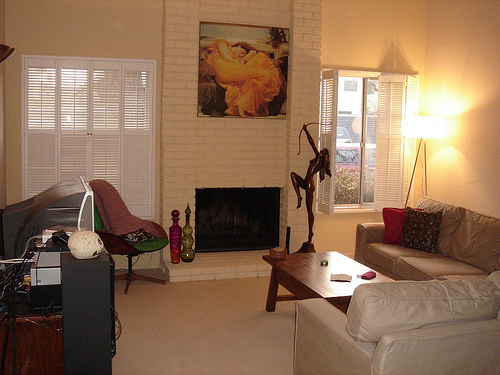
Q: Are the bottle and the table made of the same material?
A: No, the bottle is made of glass and the table is made of wood.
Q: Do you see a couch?
A: Yes, there is a couch.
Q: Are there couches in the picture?
A: Yes, there is a couch.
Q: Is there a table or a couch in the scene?
A: Yes, there is a couch.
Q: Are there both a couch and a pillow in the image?
A: Yes, there are both a couch and a pillow.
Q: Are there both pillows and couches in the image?
A: Yes, there are both a couch and a pillow.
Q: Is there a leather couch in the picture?
A: Yes, there is a couch that is made of leather.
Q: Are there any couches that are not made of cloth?
A: Yes, there is a couch that is made of leather.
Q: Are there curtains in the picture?
A: No, there are no curtains.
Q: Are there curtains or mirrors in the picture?
A: No, there are no curtains or mirrors.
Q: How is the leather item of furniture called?
A: The piece of furniture is a couch.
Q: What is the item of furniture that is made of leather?
A: The piece of furniture is a couch.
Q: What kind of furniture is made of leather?
A: The furniture is a couch.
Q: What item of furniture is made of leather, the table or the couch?
A: The couch is made of leather.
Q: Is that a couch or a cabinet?
A: That is a couch.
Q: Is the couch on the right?
A: Yes, the couch is on the right of the image.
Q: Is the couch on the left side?
A: No, the couch is on the right of the image.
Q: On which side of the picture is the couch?
A: The couch is on the right of the image.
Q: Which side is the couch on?
A: The couch is on the right of the image.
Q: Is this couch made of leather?
A: Yes, the couch is made of leather.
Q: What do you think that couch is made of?
A: The couch is made of leather.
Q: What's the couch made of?
A: The couch is made of leather.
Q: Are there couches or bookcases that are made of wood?
A: No, there is a couch but it is made of leather.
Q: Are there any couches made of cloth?
A: No, there is a couch but it is made of leather.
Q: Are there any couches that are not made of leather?
A: No, there is a couch but it is made of leather.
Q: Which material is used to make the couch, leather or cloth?
A: The couch is made of leather.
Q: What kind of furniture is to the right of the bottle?
A: The piece of furniture is a couch.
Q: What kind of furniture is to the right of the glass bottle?
A: The piece of furniture is a couch.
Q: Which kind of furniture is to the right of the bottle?
A: The piece of furniture is a couch.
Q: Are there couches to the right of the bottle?
A: Yes, there is a couch to the right of the bottle.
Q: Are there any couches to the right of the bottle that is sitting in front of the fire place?
A: Yes, there is a couch to the right of the bottle.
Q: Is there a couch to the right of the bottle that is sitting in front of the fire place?
A: Yes, there is a couch to the right of the bottle.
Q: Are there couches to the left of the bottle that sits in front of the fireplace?
A: No, the couch is to the right of the bottle.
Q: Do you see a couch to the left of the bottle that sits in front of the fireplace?
A: No, the couch is to the right of the bottle.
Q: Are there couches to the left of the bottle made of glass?
A: No, the couch is to the right of the bottle.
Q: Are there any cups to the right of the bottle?
A: No, there is a couch to the right of the bottle.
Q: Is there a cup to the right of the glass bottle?
A: No, there is a couch to the right of the bottle.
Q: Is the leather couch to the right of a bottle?
A: Yes, the couch is to the right of a bottle.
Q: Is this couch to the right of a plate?
A: No, the couch is to the right of a bottle.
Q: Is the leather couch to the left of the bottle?
A: No, the couch is to the right of the bottle.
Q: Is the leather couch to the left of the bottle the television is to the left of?
A: No, the couch is to the right of the bottle.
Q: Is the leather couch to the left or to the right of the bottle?
A: The couch is to the right of the bottle.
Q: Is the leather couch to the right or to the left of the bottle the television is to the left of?
A: The couch is to the right of the bottle.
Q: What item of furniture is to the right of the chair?
A: The piece of furniture is a couch.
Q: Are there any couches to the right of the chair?
A: Yes, there is a couch to the right of the chair.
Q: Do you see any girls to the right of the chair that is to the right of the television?
A: No, there is a couch to the right of the chair.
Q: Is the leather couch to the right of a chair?
A: Yes, the couch is to the right of a chair.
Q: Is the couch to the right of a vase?
A: No, the couch is to the right of a chair.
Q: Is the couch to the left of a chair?
A: No, the couch is to the right of a chair.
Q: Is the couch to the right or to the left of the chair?
A: The couch is to the right of the chair.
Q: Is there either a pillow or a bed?
A: Yes, there is a pillow.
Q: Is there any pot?
A: No, there are no pots.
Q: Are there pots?
A: No, there are no pots.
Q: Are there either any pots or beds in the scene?
A: No, there are no pots or beds.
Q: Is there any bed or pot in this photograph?
A: No, there are no pots or beds.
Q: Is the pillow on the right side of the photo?
A: Yes, the pillow is on the right of the image.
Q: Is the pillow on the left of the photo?
A: No, the pillow is on the right of the image.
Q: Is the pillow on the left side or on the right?
A: The pillow is on the right of the image.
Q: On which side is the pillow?
A: The pillow is on the right of the image.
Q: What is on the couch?
A: The pillow is on the couch.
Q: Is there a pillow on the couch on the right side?
A: Yes, there is a pillow on the couch.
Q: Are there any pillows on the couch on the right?
A: Yes, there is a pillow on the couch.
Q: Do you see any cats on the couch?
A: No, there is a pillow on the couch.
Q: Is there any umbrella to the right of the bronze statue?
A: No, there is a pillow to the right of the statue.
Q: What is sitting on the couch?
A: The pillow is sitting on the couch.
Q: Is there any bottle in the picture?
A: Yes, there is a bottle.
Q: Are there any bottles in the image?
A: Yes, there is a bottle.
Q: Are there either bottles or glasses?
A: Yes, there is a bottle.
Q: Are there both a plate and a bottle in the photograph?
A: No, there is a bottle but no plates.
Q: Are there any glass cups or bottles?
A: Yes, there is a glass bottle.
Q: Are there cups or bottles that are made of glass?
A: Yes, the bottle is made of glass.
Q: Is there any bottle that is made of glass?
A: Yes, there is a bottle that is made of glass.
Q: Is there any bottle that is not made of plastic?
A: Yes, there is a bottle that is made of glass.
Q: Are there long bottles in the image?
A: Yes, there is a long bottle.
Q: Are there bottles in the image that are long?
A: Yes, there is a bottle that is long.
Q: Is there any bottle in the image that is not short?
A: Yes, there is a long bottle.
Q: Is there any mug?
A: No, there are no mugs.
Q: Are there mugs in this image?
A: No, there are no mugs.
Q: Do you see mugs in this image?
A: No, there are no mugs.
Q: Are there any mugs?
A: No, there are no mugs.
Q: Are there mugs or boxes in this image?
A: No, there are no mugs or boxes.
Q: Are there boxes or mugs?
A: No, there are no mugs or boxes.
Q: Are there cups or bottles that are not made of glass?
A: No, there is a bottle but it is made of glass.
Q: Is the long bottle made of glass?
A: Yes, the bottle is made of glass.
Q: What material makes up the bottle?
A: The bottle is made of glass.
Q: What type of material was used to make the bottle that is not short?
A: The bottle is made of glass.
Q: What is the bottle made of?
A: The bottle is made of glass.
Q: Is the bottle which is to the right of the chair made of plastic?
A: No, the bottle is made of glass.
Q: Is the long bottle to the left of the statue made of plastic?
A: No, the bottle is made of glass.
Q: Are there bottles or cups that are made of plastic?
A: No, there is a bottle but it is made of glass.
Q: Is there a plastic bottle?
A: No, there is a bottle but it is made of glass.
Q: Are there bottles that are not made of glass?
A: No, there is a bottle but it is made of glass.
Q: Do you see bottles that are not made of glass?
A: No, there is a bottle but it is made of glass.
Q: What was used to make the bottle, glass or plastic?
A: The bottle is made of glass.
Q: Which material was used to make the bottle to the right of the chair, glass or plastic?
A: The bottle is made of glass.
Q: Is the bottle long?
A: Yes, the bottle is long.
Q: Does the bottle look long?
A: Yes, the bottle is long.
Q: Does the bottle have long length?
A: Yes, the bottle is long.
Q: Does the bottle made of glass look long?
A: Yes, the bottle is long.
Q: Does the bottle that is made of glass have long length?
A: Yes, the bottle is long.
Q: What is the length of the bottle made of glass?
A: The bottle is long.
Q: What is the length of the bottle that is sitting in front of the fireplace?
A: The bottle is long.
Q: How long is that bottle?
A: The bottle is long.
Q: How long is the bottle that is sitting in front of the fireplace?
A: The bottle is long.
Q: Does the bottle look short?
A: No, the bottle is long.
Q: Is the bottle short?
A: No, the bottle is long.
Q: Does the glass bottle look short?
A: No, the bottle is long.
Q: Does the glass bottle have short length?
A: No, the bottle is long.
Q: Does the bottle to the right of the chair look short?
A: No, the bottle is long.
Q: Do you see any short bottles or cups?
A: No, there is a bottle but it is long.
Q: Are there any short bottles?
A: No, there is a bottle but it is long.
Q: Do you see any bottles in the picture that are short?
A: No, there is a bottle but it is long.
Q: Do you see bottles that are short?
A: No, there is a bottle but it is long.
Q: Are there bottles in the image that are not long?
A: No, there is a bottle but it is long.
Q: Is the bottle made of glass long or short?
A: The bottle is long.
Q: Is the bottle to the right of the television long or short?
A: The bottle is long.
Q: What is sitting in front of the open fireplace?
A: The bottle is sitting in front of the fireplace.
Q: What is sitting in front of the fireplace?
A: The bottle is sitting in front of the fireplace.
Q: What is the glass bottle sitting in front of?
A: The bottle is sitting in front of the fireplace.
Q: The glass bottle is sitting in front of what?
A: The bottle is sitting in front of the fireplace.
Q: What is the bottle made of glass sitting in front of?
A: The bottle is sitting in front of the fireplace.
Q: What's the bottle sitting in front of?
A: The bottle is sitting in front of the fireplace.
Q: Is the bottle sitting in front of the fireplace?
A: Yes, the bottle is sitting in front of the fireplace.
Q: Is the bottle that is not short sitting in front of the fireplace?
A: Yes, the bottle is sitting in front of the fireplace.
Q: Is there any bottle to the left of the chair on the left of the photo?
A: No, the bottle is to the right of the chair.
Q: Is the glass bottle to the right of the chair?
A: Yes, the bottle is to the right of the chair.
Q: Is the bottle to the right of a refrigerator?
A: No, the bottle is to the right of the chair.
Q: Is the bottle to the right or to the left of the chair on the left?
A: The bottle is to the right of the chair.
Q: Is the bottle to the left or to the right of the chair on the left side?
A: The bottle is to the right of the chair.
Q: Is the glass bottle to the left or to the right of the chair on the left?
A: The bottle is to the right of the chair.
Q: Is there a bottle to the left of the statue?
A: Yes, there is a bottle to the left of the statue.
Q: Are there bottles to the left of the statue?
A: Yes, there is a bottle to the left of the statue.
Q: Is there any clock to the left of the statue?
A: No, there is a bottle to the left of the statue.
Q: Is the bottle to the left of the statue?
A: Yes, the bottle is to the left of the statue.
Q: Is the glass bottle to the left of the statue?
A: Yes, the bottle is to the left of the statue.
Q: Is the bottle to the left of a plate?
A: No, the bottle is to the left of the statue.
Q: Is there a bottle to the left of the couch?
A: Yes, there is a bottle to the left of the couch.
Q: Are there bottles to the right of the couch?
A: No, the bottle is to the left of the couch.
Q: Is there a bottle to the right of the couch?
A: No, the bottle is to the left of the couch.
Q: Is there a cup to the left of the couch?
A: No, there is a bottle to the left of the couch.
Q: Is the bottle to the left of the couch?
A: Yes, the bottle is to the left of the couch.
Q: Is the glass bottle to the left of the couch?
A: Yes, the bottle is to the left of the couch.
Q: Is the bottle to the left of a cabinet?
A: No, the bottle is to the left of the couch.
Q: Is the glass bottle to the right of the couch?
A: No, the bottle is to the left of the couch.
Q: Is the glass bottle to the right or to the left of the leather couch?
A: The bottle is to the left of the couch.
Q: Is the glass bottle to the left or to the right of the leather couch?
A: The bottle is to the left of the couch.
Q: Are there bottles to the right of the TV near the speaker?
A: Yes, there is a bottle to the right of the television.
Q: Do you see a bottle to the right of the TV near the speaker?
A: Yes, there is a bottle to the right of the television.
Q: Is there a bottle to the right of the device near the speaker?
A: Yes, there is a bottle to the right of the television.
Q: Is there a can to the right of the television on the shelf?
A: No, there is a bottle to the right of the TV.